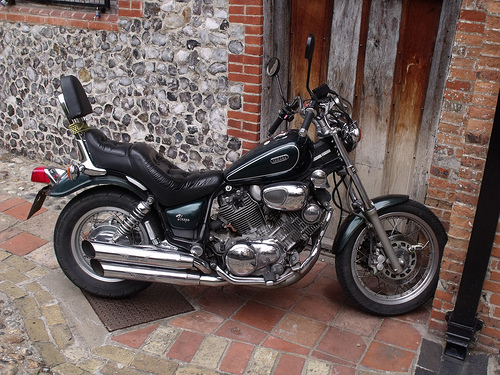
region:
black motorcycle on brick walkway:
[30, 66, 438, 307]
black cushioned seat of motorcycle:
[74, 77, 221, 197]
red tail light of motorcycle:
[23, 164, 50, 183]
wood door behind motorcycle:
[281, 4, 443, 228]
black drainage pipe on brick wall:
[430, 114, 497, 373]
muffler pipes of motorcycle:
[80, 228, 206, 287]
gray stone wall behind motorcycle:
[9, 2, 239, 191]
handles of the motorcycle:
[245, 103, 334, 150]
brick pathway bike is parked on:
[7, 182, 420, 373]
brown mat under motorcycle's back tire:
[83, 287, 205, 339]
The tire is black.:
[337, 200, 467, 305]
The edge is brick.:
[414, 10, 487, 327]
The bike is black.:
[17, 55, 425, 320]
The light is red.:
[22, 157, 48, 189]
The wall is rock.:
[5, 27, 237, 186]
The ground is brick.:
[19, 183, 386, 371]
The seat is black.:
[45, 70, 217, 207]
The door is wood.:
[274, 2, 424, 252]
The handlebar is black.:
[261, 108, 290, 142]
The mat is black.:
[81, 290, 199, 325]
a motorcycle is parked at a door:
[6, 4, 498, 374]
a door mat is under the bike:
[65, 253, 197, 336]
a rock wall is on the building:
[5, 5, 244, 180]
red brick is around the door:
[227, 5, 492, 330]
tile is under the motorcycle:
[21, 203, 423, 373]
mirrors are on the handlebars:
[263, 32, 320, 135]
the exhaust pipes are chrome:
[80, 233, 235, 284]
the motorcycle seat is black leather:
[61, 69, 228, 201]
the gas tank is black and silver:
[224, 129, 311, 181]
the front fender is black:
[331, 190, 411, 254]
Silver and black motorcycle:
[33, 37, 437, 307]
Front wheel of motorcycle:
[341, 198, 446, 311]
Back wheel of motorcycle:
[49, 183, 167, 299]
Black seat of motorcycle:
[87, 130, 220, 196]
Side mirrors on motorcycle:
[263, 35, 323, 77]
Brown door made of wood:
[286, 2, 435, 197]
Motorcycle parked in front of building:
[28, 30, 445, 308]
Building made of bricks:
[237, 1, 499, 357]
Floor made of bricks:
[2, 164, 423, 372]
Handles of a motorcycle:
[265, 109, 309, 139]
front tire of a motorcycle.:
[332, 177, 454, 327]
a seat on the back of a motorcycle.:
[77, 129, 227, 213]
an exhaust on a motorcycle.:
[75, 240, 228, 307]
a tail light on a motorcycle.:
[26, 165, 54, 185]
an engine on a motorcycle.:
[207, 208, 315, 290]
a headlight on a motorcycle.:
[309, 93, 389, 185]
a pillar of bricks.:
[414, 0, 497, 357]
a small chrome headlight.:
[329, 108, 392, 173]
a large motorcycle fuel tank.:
[206, 132, 318, 202]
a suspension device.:
[89, 190, 165, 256]